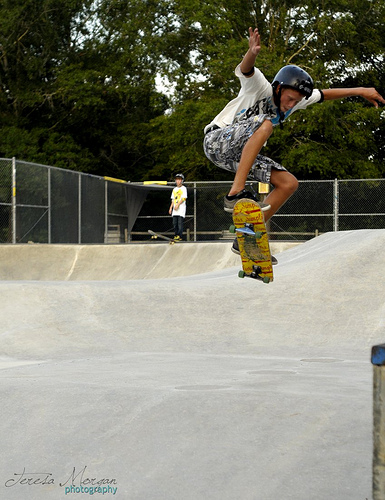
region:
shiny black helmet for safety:
[269, 65, 313, 97]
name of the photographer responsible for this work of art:
[3, 465, 116, 495]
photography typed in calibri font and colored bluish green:
[62, 486, 118, 496]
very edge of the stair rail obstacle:
[369, 344, 384, 498]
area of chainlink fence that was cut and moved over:
[125, 183, 147, 234]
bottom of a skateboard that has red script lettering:
[231, 197, 274, 282]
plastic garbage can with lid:
[102, 223, 120, 243]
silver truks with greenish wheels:
[227, 222, 261, 237]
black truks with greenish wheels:
[235, 263, 269, 282]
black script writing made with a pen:
[4, 465, 115, 488]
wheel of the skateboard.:
[227, 221, 238, 234]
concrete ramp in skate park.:
[306, 257, 367, 314]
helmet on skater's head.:
[273, 68, 309, 98]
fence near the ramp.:
[59, 183, 71, 233]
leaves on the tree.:
[75, 79, 93, 97]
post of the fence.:
[9, 163, 17, 207]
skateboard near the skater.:
[146, 227, 176, 242]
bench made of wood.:
[223, 229, 230, 240]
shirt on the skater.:
[237, 84, 266, 110]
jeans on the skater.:
[177, 218, 183, 234]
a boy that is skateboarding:
[151, 20, 349, 306]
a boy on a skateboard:
[158, 31, 354, 322]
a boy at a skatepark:
[56, 37, 384, 393]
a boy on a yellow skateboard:
[158, 15, 383, 333]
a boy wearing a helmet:
[175, 24, 357, 160]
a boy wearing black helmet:
[196, 22, 383, 205]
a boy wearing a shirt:
[185, 23, 347, 200]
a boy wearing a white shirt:
[199, 3, 339, 196]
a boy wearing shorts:
[201, 39, 336, 244]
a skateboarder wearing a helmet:
[188, 9, 360, 265]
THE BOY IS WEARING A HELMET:
[272, 56, 313, 122]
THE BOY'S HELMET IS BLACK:
[265, 59, 319, 122]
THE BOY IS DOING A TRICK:
[199, 18, 383, 296]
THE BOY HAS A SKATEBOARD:
[225, 191, 274, 294]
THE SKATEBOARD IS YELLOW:
[223, 196, 275, 293]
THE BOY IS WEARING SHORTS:
[201, 106, 290, 202]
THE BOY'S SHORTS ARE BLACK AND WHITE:
[201, 119, 289, 190]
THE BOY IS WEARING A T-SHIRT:
[197, 56, 326, 145]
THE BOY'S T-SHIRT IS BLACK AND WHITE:
[204, 60, 335, 143]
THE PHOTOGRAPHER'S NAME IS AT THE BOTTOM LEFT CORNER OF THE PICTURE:
[0, 460, 147, 496]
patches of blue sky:
[70, 0, 382, 101]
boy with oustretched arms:
[206, 25, 379, 201]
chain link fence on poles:
[8, 155, 384, 246]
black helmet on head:
[272, 64, 314, 95]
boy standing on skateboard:
[149, 173, 188, 242]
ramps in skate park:
[7, 229, 382, 356]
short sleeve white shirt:
[213, 64, 322, 138]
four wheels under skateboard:
[232, 197, 272, 285]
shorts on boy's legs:
[206, 117, 291, 185]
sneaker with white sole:
[223, 193, 270, 216]